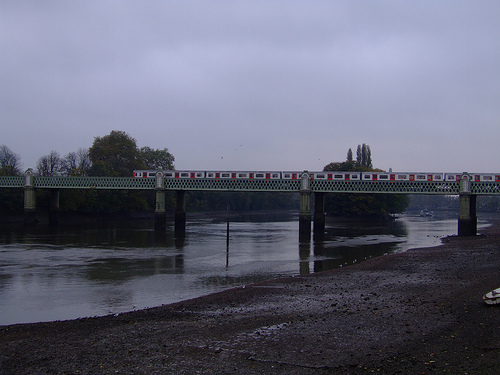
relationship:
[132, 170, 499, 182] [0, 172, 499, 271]
red train on bridge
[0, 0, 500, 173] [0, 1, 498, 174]
cloud in sky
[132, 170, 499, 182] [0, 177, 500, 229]
red train on bridge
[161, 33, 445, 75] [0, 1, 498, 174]
cloud in sky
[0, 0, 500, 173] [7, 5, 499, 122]
cloud in sky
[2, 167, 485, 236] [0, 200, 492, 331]
bridge over water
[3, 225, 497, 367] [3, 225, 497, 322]
wet sand next to water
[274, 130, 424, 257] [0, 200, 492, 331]
trees in middle of water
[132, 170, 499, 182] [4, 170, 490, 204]
red train going over bridge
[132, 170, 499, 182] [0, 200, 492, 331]
red train traveling over water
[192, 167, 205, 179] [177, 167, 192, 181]
white trim around window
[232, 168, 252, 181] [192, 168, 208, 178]
white trim around window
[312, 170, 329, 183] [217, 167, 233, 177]
white trim around window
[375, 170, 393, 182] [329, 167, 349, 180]
white trim around window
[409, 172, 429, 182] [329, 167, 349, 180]
white trim around window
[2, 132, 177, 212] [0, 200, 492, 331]
trees opposite of water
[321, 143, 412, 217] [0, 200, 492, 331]
trees opposite of water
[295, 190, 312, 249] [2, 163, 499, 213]
pillar under bridge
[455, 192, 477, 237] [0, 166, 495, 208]
pillar under bridge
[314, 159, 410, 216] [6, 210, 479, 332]
tree next to water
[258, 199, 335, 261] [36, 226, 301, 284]
column in water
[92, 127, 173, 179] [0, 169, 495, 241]
tree behind bridge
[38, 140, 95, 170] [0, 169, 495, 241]
tree behind bridge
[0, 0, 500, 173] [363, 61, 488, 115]
cloud in sky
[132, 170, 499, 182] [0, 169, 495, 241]
red train on bridge